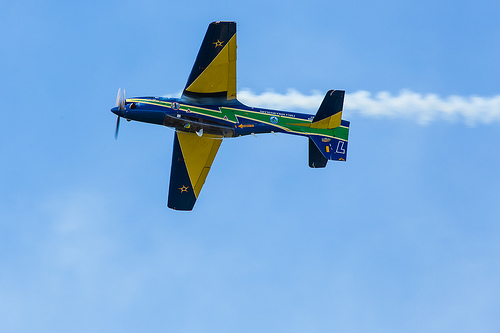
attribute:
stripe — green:
[270, 79, 307, 114]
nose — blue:
[102, 85, 242, 227]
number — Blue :
[255, 85, 307, 121]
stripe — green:
[126, 95, 349, 142]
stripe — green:
[125, 97, 352, 147]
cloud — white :
[40, 193, 120, 278]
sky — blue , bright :
[2, 1, 478, 328]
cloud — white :
[258, 230, 316, 297]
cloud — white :
[282, 246, 346, 298]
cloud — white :
[48, 188, 131, 289]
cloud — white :
[17, 17, 81, 84]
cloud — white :
[41, 178, 107, 248]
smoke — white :
[164, 87, 497, 124]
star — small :
[178, 183, 191, 193]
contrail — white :
[168, 91, 495, 121]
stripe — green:
[157, 92, 348, 146]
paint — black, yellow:
[115, 19, 365, 212]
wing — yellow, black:
[156, 115, 239, 218]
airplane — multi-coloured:
[96, 18, 359, 215]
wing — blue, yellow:
[310, 91, 350, 127]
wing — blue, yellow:
[307, 137, 338, 172]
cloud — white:
[238, 87, 486, 121]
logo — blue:
[265, 110, 281, 129]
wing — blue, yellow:
[168, 16, 242, 96]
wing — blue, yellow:
[170, 125, 230, 211]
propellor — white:
[112, 83, 130, 144]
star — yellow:
[213, 39, 223, 49]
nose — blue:
[102, 90, 134, 128]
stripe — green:
[135, 88, 349, 151]